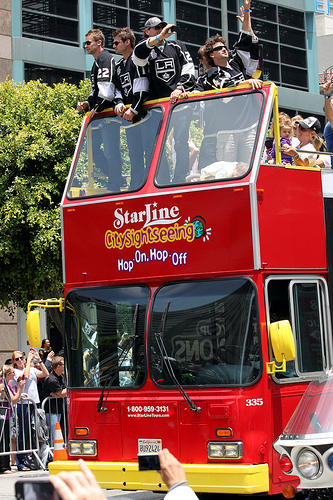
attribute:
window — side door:
[256, 269, 329, 396]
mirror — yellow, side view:
[265, 318, 296, 379]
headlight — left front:
[192, 438, 247, 462]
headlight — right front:
[59, 420, 287, 462]